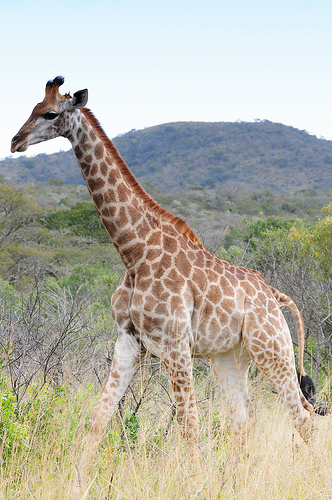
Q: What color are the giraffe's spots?
A: Brown.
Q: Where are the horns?
A: On the giraffe's head.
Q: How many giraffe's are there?
A: 1.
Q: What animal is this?
A: Giraffe.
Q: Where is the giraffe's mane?
A: On the neck.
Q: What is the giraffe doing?
A: Walking.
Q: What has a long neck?
A: A giraffe.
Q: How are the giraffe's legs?
A: Long.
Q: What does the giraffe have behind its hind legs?
A: A tail.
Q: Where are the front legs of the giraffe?
A: In the grass.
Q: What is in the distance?
A: A portion of a mountain range.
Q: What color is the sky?
A: Blue.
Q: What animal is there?
A: A giraffe.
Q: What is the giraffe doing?
A: Walking.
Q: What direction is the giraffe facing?
A: Left.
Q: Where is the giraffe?
A: Tall grass.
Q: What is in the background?
A: Mountain.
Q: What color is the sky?
A: Blue.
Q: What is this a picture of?
A: Giraffe.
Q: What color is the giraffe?
A: Brown and white.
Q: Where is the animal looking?
A: To the side.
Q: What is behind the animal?
A: A mountain.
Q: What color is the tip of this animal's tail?
A: Black.